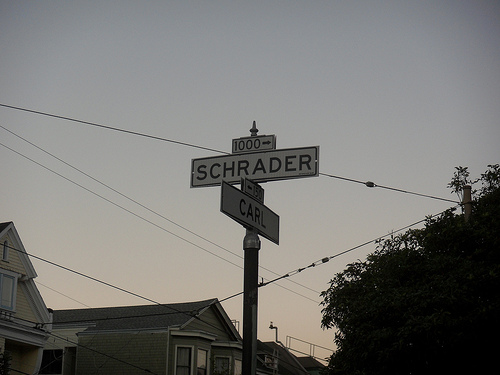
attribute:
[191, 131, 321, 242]
road signs — four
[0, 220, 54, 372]
house — single, yellow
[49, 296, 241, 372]
house — yellow, single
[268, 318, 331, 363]
searcher — metal, signal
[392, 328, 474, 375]
leaves — green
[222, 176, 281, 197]
sign —  tall and metal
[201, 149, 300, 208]
sign —  metal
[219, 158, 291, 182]
sign —  metal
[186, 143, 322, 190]
street sign — white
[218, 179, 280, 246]
street sign — white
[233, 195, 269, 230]
text — black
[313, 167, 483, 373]
hedge — green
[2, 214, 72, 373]
house — yellow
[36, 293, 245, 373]
house — yellow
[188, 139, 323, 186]
street sign — white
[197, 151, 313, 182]
text — black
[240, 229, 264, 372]
sign post — gray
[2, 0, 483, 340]
sky — dusk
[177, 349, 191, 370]
curtains — white